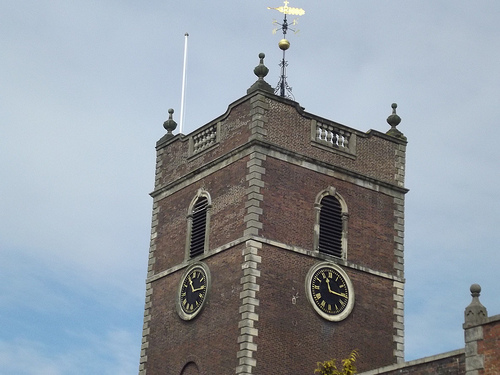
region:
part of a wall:
[318, 200, 338, 221]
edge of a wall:
[251, 270, 272, 326]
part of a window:
[332, 225, 348, 258]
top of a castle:
[277, 123, 289, 141]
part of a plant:
[349, 341, 353, 357]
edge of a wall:
[256, 262, 278, 311]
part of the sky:
[71, 276, 90, 324]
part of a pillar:
[461, 248, 476, 309]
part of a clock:
[308, 283, 334, 312]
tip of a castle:
[250, 83, 272, 122]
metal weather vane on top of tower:
[266, 3, 306, 100]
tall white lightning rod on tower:
[178, 30, 189, 131]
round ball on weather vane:
[279, 38, 289, 50]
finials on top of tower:
[247, 51, 273, 92]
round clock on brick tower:
[306, 262, 356, 322]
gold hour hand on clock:
[323, 277, 330, 292]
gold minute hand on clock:
[328, 288, 348, 300]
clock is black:
[306, 260, 352, 319]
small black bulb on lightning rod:
[185, 31, 190, 35]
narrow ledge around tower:
[150, 135, 409, 195]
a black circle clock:
[307, 262, 356, 315]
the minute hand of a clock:
[331, 288, 348, 303]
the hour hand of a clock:
[323, 277, 333, 291]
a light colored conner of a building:
[230, 93, 270, 373]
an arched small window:
[312, 186, 351, 263]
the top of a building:
[146, 73, 406, 187]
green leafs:
[315, 352, 365, 374]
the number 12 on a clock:
[326, 268, 335, 280]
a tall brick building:
[130, 12, 428, 374]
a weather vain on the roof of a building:
[265, 0, 313, 99]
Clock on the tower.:
[194, 197, 438, 369]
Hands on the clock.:
[276, 232, 360, 320]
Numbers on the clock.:
[295, 223, 374, 327]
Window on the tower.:
[278, 140, 375, 284]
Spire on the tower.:
[249, 4, 357, 131]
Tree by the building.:
[289, 337, 394, 373]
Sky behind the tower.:
[59, 30, 203, 198]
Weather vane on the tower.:
[263, 7, 330, 85]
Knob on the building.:
[428, 249, 487, 309]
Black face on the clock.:
[297, 242, 362, 348]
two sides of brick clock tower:
[141, 50, 416, 373]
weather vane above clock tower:
[268, 0, 310, 100]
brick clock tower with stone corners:
[135, 3, 412, 374]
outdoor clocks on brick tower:
[173, 255, 355, 322]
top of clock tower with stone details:
[148, 49, 412, 163]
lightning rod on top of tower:
[171, 29, 193, 136]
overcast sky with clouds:
[13, 12, 135, 322]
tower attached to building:
[133, 50, 499, 374]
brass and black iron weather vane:
[251, 2, 312, 98]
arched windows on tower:
[181, 181, 360, 263]